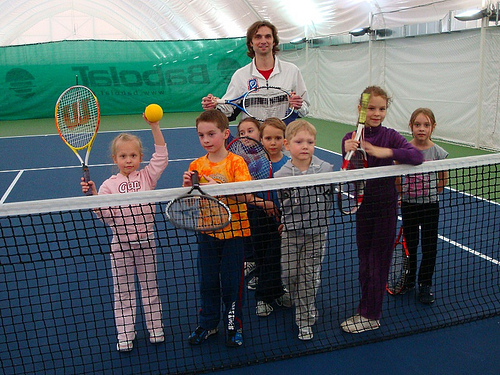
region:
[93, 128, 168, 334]
young child ready to play tennis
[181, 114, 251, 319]
young child ready to play tennis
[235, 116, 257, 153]
young child ready to play tennis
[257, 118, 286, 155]
young child ready to play tennis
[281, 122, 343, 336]
young child ready to play tennis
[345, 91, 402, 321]
young child ready to play tennis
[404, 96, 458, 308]
young child ready to play tennis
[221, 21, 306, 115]
man ready to teach tennis lesson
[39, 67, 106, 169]
young child holding tennis racquet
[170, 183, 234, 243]
young child holding tennis racquet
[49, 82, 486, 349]
children on a tennis court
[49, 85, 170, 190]
girl holding up a tennis ball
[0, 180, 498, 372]
netting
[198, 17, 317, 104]
tennis coach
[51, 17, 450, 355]
children with their tennis coach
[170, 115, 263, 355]
boy holding a tennis racket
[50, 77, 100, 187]
tennis racket with a W on it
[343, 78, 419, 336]
girl wearing purple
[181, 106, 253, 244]
boy with an orange shirt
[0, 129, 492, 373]
blue tennis court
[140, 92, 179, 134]
Yellow kid style tennis ball.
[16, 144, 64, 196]
Blue colored tennis court.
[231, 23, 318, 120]
Tennis instructor with white jacket.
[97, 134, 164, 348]
Little girl in all pink outfit.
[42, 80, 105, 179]
Orange and red tennis racket.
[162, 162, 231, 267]
Black and silver tennis racket.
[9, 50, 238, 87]
Green side of tent with advertisement.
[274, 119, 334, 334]
Blonde boy with all grey suit.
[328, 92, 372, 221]
White and red tennis racket.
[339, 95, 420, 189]
Little girl with purple shirt.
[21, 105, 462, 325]
kids standing on tennis court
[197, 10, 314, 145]
couch standing on tennis court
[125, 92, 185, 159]
girl holding yellow tennis ball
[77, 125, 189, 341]
girl wearing pink track suit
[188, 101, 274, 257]
boy wearing orange tie and dye shirt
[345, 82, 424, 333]
girl wearing purple track suit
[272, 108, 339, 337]
boy wearing grey track suit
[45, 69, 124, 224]
girl holding orange and yellow tennis racket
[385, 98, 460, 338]
girl wearing black pants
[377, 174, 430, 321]
girl holding black and red tennis racket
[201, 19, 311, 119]
Man behind a group of kids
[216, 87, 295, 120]
Racket in the man's hands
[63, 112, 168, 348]
Girl wearing pink sweater and pants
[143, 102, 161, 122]
Yellow ball in the girl's left hand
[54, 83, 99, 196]
Racket in the girl's right hand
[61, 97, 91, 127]
Letter on the racket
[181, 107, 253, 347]
Boy with orange shirt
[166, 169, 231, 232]
Racket in the boy's hands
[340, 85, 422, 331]
Girl with purple shirt and perple pants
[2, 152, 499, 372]
Net on a tennis court